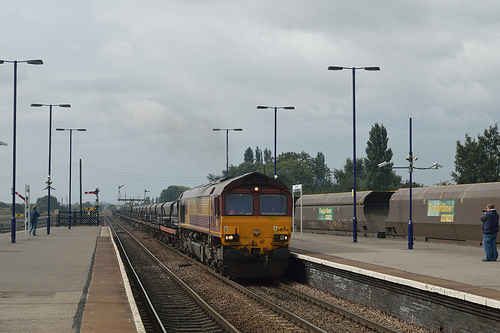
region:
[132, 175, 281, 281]
Train pulling into the station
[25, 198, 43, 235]
person standing on a train platform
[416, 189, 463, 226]
label on a train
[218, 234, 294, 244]
lights on the train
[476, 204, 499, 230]
man wearing a blue jacket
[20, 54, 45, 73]
lights on a pole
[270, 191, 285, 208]
windshield wiper on a windshield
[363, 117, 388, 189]
leaves on a tree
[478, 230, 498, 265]
man wearing blue trees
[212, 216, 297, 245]
yellow paint on a train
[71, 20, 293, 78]
cluster of clouds in sky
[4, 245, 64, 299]
sidewalk of bus station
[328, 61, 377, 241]
street lamp for lighting the night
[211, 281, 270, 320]
bed of rocks around tracks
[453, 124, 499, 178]
tree on side of tacks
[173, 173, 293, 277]
front cart of train for conductor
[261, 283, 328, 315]
railroad tracks for trains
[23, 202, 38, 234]
person standing on the side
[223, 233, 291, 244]
train lights for night time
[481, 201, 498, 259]
person with coat standing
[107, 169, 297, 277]
Large yellow train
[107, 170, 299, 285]
Industrial train on train tracks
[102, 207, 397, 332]
Two lane train tracks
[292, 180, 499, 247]
Two metal train cars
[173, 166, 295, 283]
Front car of a train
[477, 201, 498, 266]
Man standing on a train platform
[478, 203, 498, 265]
Man wearing a sweatshirt and blue jeans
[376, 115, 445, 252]
Two security cameras on a pole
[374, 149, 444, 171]
Two white cameras and speakers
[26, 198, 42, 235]
Person walking on a train platform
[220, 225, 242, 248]
light on the front of a train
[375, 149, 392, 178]
a camera on a pole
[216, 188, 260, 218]
a window on the front of a train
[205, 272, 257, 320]
gravel between the train tracks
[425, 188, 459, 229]
a sign on a train car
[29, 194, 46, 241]
a person walking on a sidewalk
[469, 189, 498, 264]
a man standing near the train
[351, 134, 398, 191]
a tree behind the train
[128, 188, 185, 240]
train cars attached to the train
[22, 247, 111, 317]
sidewalk next to the train tracks